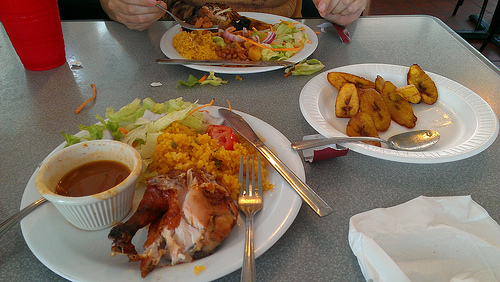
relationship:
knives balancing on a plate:
[155, 56, 335, 218] [21, 104, 298, 273]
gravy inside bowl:
[53, 158, 130, 195] [41, 127, 144, 237]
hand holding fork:
[108, 0, 171, 31] [151, 6, 225, 35]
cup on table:
[1, 0, 77, 80] [0, 15, 498, 280]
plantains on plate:
[121, 47, 462, 203] [291, 0, 493, 103]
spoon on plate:
[289, 127, 447, 155] [447, 107, 497, 164]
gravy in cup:
[53, 158, 130, 195] [33, 137, 139, 231]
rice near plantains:
[147, 121, 272, 191] [121, 47, 462, 203]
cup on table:
[1, 0, 77, 80] [324, 13, 497, 246]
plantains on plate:
[121, 47, 462, 203] [21, 104, 298, 273]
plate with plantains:
[294, 54, 485, 168] [326, 66, 441, 133]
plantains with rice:
[121, 47, 462, 203] [149, 116, 274, 198]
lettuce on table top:
[147, 57, 330, 86] [1, 13, 496, 280]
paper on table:
[336, 191, 497, 281] [370, 8, 497, 63]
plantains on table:
[121, 47, 462, 203] [0, 15, 498, 280]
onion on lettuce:
[243, 24, 273, 38] [266, 17, 289, 53]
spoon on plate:
[289, 127, 447, 155] [297, 59, 499, 175]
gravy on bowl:
[53, 158, 130, 195] [26, 131, 153, 236]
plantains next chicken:
[121, 47, 462, 203] [130, 182, 247, 279]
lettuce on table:
[147, 57, 330, 86] [0, 15, 498, 280]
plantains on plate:
[121, 47, 462, 203] [57, 17, 499, 223]